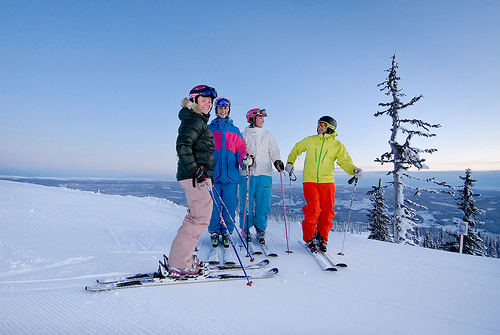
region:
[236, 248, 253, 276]
part of a hokker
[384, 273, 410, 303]
part of a snwo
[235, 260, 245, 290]
par tof a hokker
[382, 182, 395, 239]
part of a tree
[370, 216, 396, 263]
part of a tree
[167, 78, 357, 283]
group of people on skies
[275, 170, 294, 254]
the pink ski pole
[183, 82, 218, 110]
the pink helmet under the blue googles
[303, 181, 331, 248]
teh red pants on the man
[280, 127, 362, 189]
the bright yellow jacket on the man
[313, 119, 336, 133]
the yllow straps to the orange tinted googles.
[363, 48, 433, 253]
the cnow covered tree behind the skiers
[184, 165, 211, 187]
the hand of the women holds the ski pole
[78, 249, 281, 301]
the skis straped to the pink boots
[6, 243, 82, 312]
the ski marks in the snow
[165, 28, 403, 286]
four people on snow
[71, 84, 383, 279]
people are on skis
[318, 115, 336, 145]
person has black helmet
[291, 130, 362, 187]
person has yellow jacket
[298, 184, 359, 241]
person has orange pants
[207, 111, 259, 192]
blue and pink jacket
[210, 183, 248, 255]
person has dark blue pants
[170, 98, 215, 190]
person has black jacket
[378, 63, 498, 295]
skeletal trees beside people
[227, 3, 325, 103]
sky is blue and clear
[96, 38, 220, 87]
the sky is blue in colour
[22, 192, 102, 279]
the snow is white in colour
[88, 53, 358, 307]
people are getting ready to skii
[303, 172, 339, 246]
the pants are red in colour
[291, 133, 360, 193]
the jacket is yellow in colour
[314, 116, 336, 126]
the helmet is black in colour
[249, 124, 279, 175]
the jacket is white in colour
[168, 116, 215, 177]
the jacket is black in colour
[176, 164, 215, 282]
the pants are brown in colour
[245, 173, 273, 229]
the trouser is blue in colour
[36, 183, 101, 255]
the snow is on the ground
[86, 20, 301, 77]
the sky is blue in colour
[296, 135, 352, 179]
the jacket is yellow in coloour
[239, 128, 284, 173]
the shirt is white in colour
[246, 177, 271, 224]
the pants are blue in colour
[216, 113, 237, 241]
the outfit is blue in colour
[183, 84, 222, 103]
the goggles are black in colour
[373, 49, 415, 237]
the tree is covered in snow